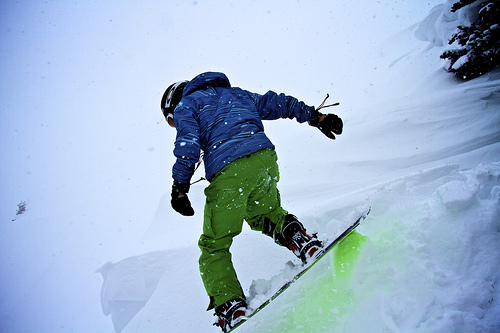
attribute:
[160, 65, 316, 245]
person — young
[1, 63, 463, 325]
snow — white, untouched, disturbed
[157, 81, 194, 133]
helmet — black, white, ski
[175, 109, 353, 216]
gloves — pair, black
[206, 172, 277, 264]
pants — green, snow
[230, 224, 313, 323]
boots — red, white, black, ski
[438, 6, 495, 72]
tree — green, pine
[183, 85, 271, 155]
snow coat — blue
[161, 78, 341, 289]
snowboarder — boarding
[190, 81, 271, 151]
coat — blue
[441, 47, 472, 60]
limbs — snow covered, snowy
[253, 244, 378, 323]
reflection — green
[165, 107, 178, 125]
snow goggles — white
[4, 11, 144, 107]
sky — blue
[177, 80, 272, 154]
jacket — ocean blue, light blue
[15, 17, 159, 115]
clouds — white